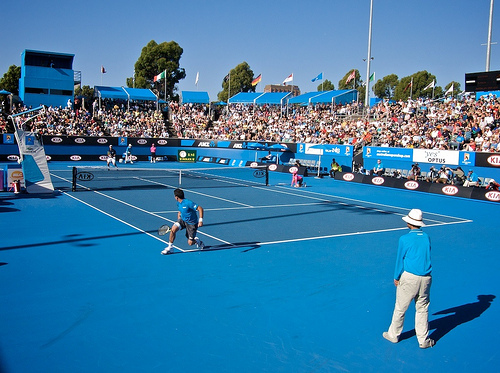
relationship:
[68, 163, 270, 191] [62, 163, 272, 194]
net tennis courts net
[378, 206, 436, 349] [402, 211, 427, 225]
man wearing hat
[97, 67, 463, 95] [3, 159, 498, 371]
flags around court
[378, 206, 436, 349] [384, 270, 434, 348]
man wearing pants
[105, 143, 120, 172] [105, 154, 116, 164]
player wearing shorts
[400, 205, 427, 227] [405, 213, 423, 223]
hat has band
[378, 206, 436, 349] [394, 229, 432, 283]
man wearing shirt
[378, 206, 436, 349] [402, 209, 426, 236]
man wearing hat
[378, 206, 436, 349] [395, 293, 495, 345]
man casting shadow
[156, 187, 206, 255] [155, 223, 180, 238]
man holding racquet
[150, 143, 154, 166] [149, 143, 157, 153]
person wearing shirt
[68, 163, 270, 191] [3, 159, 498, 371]
net on court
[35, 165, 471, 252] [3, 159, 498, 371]
lines on court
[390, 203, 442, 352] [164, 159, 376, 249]
man standing on court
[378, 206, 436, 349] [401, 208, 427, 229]
man wearing a hat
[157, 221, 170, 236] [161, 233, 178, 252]
racquet beside leg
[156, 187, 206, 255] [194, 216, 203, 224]
man has on a armband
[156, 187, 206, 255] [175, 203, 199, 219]
man has on a shirt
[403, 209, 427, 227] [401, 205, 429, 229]
hat on head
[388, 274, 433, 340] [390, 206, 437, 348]
pants are on man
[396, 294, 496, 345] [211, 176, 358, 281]
shadow are on court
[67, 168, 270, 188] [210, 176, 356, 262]
net over court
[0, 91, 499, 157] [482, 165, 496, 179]
crowd are watching from bleacher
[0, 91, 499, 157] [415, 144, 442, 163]
crowd are watching from bleacher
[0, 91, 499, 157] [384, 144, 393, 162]
crowd are watching from bleacher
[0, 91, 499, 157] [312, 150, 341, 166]
crowd are watching from bleacher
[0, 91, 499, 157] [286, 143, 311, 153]
crowd are watching from bleacher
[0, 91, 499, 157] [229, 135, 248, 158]
crowd are watching from bleacher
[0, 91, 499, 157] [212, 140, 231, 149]
crowd are watching from bleacher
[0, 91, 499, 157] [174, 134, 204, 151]
crowd are watching from bleacher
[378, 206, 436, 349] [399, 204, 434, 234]
man wearing hat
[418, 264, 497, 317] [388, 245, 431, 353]
shadow of man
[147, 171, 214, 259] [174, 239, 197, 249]
man kneeling down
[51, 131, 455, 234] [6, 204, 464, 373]
lines on court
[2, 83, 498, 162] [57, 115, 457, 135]
crowd of people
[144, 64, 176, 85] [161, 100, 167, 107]
flag on pole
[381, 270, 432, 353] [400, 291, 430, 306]
pair of pants